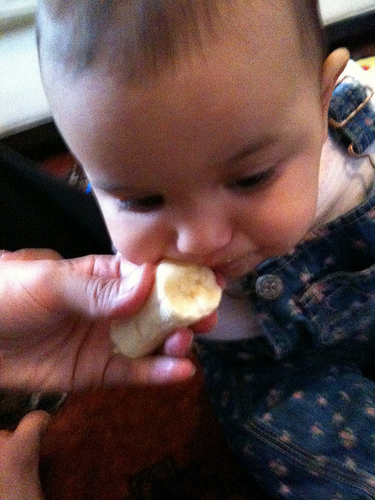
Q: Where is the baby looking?
A: Away from banana.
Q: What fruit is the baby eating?
A: Banana.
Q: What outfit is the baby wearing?
A: Overalls.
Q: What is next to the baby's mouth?
A: Banana.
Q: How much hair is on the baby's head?
A: Sparse.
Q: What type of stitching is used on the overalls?
A: Triple.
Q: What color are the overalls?
A: Blue.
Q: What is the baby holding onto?
A: Fuzzy toy.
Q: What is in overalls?
A: Baby.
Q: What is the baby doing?
A: Eating.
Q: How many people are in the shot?
A: Two.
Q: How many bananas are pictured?
A: One.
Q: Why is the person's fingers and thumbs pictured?
A: Giving food.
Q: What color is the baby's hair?
A: Brown.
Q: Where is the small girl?
A: Eating.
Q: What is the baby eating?
A: Banana.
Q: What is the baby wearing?
A: Overalls.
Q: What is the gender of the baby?
A: Girl.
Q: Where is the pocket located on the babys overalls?
A: Front.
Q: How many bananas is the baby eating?
A: One.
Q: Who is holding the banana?
A: Adult.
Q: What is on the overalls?
A: Flowers.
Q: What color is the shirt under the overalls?
A: White.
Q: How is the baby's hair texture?
A: Fine.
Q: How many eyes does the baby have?
A: Two.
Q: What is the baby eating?
A: A banana.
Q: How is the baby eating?
A: Her mouth.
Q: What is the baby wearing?
A: Overalls.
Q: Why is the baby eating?
A: She's hungry.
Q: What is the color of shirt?
A: Pink.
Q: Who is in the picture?
A: A baby.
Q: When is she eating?
A: During the day.